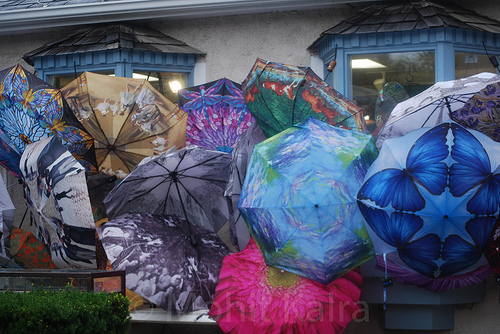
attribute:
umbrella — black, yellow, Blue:
[1, 64, 98, 178]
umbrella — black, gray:
[89, 142, 239, 224]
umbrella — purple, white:
[88, 200, 250, 317]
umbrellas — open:
[0, 52, 497, 277]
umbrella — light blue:
[354, 118, 498, 278]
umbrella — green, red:
[238, 57, 369, 138]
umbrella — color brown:
[58, 68, 189, 179]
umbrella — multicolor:
[359, 130, 498, 282]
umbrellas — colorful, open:
[2, 55, 495, 327]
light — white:
[341, 52, 391, 83]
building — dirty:
[0, 0, 492, 333]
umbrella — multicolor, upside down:
[239, 43, 373, 141]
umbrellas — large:
[43, 37, 489, 329]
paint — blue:
[32, 57, 197, 90]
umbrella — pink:
[204, 248, 382, 328]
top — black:
[33, 22, 193, 72]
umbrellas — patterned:
[145, 133, 426, 221]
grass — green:
[8, 278, 128, 330]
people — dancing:
[89, 82, 162, 134]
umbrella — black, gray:
[17, 134, 101, 273]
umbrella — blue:
[196, 97, 376, 295]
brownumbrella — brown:
[62, 67, 188, 184]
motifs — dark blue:
[354, 121, 499, 279]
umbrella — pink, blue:
[176, 75, 258, 160]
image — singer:
[112, 230, 177, 296]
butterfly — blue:
[361, 163, 453, 213]